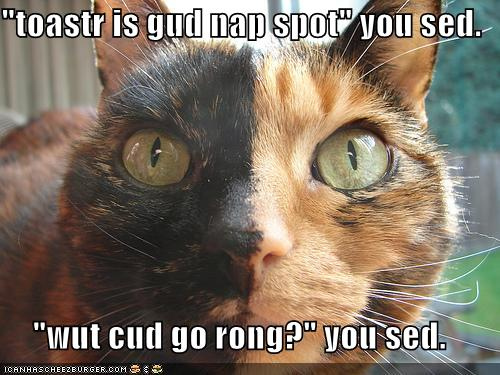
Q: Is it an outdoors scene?
A: Yes, it is outdoors.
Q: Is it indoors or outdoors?
A: It is outdoors.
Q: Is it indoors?
A: No, it is outdoors.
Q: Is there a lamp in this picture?
A: No, there are no lamps.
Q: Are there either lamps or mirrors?
A: No, there are no lamps or mirrors.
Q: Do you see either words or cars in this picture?
A: Yes, there are words.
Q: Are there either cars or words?
A: Yes, there are words.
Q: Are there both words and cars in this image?
A: No, there are words but no cars.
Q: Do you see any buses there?
A: No, there are no buses.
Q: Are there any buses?
A: No, there are no buses.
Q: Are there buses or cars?
A: No, there are no buses or cars.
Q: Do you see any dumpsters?
A: No, there are no dumpsters.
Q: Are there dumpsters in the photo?
A: No, there are no dumpsters.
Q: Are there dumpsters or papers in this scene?
A: No, there are no dumpsters or papers.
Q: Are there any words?
A: Yes, there are words.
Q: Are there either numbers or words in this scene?
A: Yes, there are words.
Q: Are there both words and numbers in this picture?
A: No, there are words but no numbers.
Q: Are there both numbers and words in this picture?
A: No, there are words but no numbers.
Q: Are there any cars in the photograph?
A: No, there are no cars.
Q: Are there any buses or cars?
A: No, there are no cars or buses.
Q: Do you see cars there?
A: No, there are no cars.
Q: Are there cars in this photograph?
A: No, there are no cars.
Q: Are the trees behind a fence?
A: Yes, the trees are behind a fence.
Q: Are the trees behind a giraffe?
A: No, the trees are behind a fence.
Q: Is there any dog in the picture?
A: No, there are no dogs.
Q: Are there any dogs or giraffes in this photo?
A: No, there are no dogs or giraffes.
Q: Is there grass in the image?
A: Yes, there is grass.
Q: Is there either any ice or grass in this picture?
A: Yes, there is grass.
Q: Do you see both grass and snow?
A: No, there is grass but no snow.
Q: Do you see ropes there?
A: No, there are no ropes.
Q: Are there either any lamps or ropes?
A: No, there are no ropes or lamps.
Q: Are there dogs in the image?
A: No, there are no dogs.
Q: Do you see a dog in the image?
A: No, there are no dogs.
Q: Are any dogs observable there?
A: No, there are no dogs.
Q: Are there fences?
A: Yes, there is a fence.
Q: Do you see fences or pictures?
A: Yes, there is a fence.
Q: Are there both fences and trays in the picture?
A: No, there is a fence but no trays.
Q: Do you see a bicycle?
A: No, there are no bicycles.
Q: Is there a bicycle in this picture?
A: No, there are no bicycles.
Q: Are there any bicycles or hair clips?
A: No, there are no bicycles or hair clips.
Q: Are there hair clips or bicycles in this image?
A: No, there are no bicycles or hair clips.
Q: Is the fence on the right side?
A: Yes, the fence is on the right of the image.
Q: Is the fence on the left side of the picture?
A: No, the fence is on the right of the image.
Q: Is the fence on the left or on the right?
A: The fence is on the right of the image.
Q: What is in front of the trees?
A: The fence is in front of the trees.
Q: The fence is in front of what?
A: The fence is in front of the trees.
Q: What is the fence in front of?
A: The fence is in front of the trees.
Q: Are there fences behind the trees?
A: No, the fence is in front of the trees.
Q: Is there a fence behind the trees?
A: No, the fence is in front of the trees.